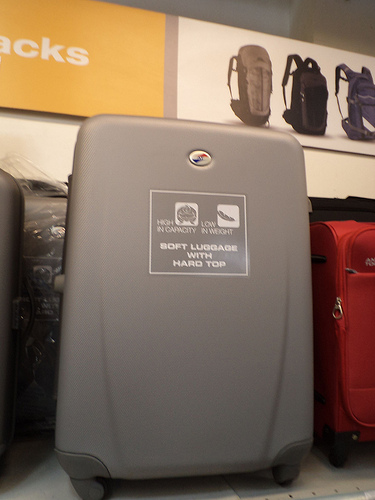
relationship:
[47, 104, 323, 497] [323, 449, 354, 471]
luggage has wheels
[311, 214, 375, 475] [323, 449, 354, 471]
luggage has wheels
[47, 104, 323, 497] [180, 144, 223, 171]
luggage has logo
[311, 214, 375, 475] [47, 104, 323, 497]
red luggage near luggage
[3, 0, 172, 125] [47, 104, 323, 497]
sign behind luggage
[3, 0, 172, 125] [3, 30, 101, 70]
sign has letters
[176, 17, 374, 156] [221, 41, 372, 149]
picture has picture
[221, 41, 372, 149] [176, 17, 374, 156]
picture on picture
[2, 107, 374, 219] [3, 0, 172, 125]
wall under sign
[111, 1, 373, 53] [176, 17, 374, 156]
ceiling above picture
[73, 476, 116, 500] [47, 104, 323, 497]
wheel on luggage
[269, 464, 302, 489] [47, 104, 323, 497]
wheel on luggage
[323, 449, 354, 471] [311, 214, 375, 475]
wheel on luggage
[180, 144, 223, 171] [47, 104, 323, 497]
logo on luggage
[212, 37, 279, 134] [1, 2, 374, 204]
illustrations are on wall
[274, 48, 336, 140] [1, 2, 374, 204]
illustrations are on wall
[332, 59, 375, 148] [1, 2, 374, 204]
illustrations are on wall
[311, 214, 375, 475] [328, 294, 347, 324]
luggage has zipper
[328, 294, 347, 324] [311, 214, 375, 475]
zipper on luggage